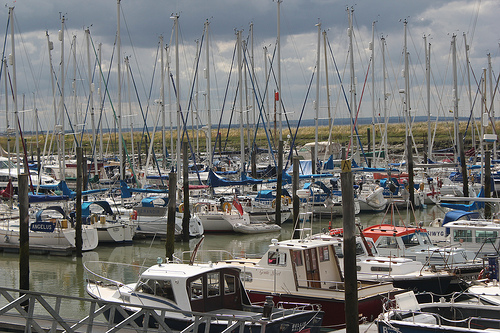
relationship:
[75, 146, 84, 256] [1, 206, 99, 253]
pole near boat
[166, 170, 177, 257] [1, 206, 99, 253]
pole near boat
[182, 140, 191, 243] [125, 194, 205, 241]
pole near boat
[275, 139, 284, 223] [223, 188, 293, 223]
pole near boat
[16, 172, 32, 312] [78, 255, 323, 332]
pole near boat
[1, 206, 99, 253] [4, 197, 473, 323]
boat in water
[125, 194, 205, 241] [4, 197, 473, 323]
boat in water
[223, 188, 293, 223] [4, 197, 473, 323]
boat in water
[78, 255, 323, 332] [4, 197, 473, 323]
boat in water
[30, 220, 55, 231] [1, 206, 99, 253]
sign on boat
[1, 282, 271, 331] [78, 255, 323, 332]
walkway to boat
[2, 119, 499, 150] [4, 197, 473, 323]
field behind water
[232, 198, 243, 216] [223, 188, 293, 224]
flag on boat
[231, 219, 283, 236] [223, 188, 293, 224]
dingy tied to boat